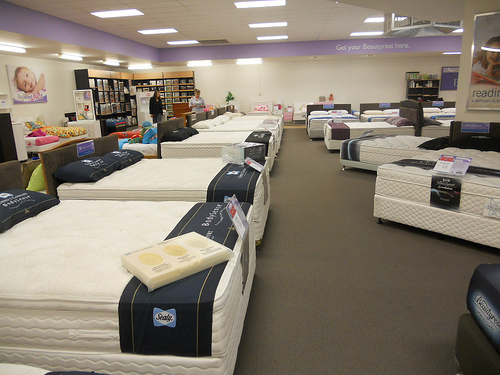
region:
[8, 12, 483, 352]
mattresses in a room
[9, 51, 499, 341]
these mattresses are on display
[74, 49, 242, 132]
these people are looking at mattresses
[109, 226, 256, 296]
a bedding object on the mattress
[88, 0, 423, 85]
lights on the ceiling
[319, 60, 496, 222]
these are full size mattresses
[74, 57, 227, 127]
a display case on the sales floor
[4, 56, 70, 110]
a baby picture's on the wall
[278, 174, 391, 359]
a dark brown carpet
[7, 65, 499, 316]
fourteen mattresses are in this picture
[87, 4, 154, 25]
a fluorescent light in the ceiling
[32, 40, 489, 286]
mattresses in a store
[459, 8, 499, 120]
a framed advertisement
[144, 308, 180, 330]
a brand logo and name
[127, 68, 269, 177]
people in a store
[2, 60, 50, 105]
a picture of a baby on a wall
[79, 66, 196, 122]
items on a shelf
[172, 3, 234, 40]
drop ceiling tiles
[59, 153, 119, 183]
a black pillow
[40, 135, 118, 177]
the head board for a bed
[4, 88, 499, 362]
showroom for mattresses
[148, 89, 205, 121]
two people in the showroom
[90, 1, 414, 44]
lights in the ceiling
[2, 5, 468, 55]
purple border on the wall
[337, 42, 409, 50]
white lettering on purple background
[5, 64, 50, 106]
picture hanging on the wall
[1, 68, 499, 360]
rows of white mattresses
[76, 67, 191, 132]
black display against the back wall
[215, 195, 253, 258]
information sheets attached to the mattress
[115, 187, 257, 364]
navy banner draped on mattress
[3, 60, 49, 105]
baby face in poster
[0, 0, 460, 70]
Sixteen lights on ceiling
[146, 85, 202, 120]
sales woman and customer walking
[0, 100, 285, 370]
aligned beds for sale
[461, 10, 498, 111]
poster with words and picture on wall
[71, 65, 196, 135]
bookshelves on corner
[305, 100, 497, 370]
beds, not in line, for sale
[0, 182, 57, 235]
blue pillow for sale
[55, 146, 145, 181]
blue pillows for sale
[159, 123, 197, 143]
blue pillows for sale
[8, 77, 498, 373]
several white mattresses in store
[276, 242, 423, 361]
section of gray commercial carpet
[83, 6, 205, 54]
row of rectangular shaped fluorescent lights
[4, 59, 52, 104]
rectangular shaped picture of child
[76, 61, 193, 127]
rows of black and brown wooden shelves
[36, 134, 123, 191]
rectangular shaped dark headboard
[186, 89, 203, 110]
one woman wearing light colored shirt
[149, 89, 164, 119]
one person wearing dark colored shirt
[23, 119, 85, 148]
several multi-colored pillows on bed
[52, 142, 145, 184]
two rectangular black bed pillows